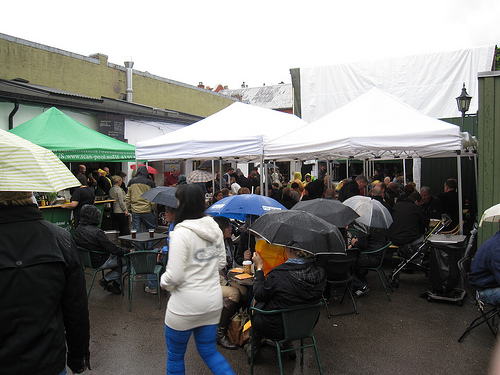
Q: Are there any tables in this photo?
A: Yes, there is a table.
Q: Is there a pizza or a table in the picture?
A: Yes, there is a table.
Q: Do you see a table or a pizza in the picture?
A: Yes, there is a table.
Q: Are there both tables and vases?
A: No, there is a table but no vases.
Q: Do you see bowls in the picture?
A: No, there are no bowls.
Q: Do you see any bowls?
A: No, there are no bowls.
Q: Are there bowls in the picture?
A: No, there are no bowls.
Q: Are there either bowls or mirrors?
A: No, there are no bowls or mirrors.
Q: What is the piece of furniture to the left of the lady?
A: The piece of furniture is a table.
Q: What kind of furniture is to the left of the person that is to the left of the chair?
A: The piece of furniture is a table.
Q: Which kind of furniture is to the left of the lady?
A: The piece of furniture is a table.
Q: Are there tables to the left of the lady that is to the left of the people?
A: Yes, there is a table to the left of the lady.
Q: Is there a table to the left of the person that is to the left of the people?
A: Yes, there is a table to the left of the lady.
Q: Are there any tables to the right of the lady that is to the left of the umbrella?
A: No, the table is to the left of the lady.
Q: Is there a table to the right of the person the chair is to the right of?
A: No, the table is to the left of the lady.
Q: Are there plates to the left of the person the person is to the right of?
A: No, there is a table to the left of the lady.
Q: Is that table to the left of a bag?
A: No, the table is to the left of a lady.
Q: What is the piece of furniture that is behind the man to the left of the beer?
A: The piece of furniture is a table.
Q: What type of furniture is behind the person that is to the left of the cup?
A: The piece of furniture is a table.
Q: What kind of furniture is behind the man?
A: The piece of furniture is a table.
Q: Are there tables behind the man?
A: Yes, there is a table behind the man.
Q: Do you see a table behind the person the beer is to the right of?
A: Yes, there is a table behind the man.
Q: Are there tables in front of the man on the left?
A: No, the table is behind the man.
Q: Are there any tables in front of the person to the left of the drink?
A: No, the table is behind the man.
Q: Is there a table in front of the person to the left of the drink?
A: No, the table is behind the man.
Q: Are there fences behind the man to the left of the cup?
A: No, there is a table behind the man.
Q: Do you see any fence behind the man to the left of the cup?
A: No, there is a table behind the man.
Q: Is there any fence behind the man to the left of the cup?
A: No, there is a table behind the man.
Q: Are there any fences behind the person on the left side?
A: No, there is a table behind the man.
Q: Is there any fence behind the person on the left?
A: No, there is a table behind the man.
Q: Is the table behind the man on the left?
A: Yes, the table is behind the man.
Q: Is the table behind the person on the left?
A: Yes, the table is behind the man.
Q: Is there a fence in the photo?
A: No, there are no fences.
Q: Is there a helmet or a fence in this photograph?
A: No, there are no fences or helmets.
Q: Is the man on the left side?
A: Yes, the man is on the left of the image.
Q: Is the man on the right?
A: No, the man is on the left of the image.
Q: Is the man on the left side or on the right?
A: The man is on the left of the image.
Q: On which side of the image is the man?
A: The man is on the left of the image.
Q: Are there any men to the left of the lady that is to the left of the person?
A: Yes, there is a man to the left of the lady.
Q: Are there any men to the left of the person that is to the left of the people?
A: Yes, there is a man to the left of the lady.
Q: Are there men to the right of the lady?
A: No, the man is to the left of the lady.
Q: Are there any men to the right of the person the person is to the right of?
A: No, the man is to the left of the lady.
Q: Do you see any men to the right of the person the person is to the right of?
A: No, the man is to the left of the lady.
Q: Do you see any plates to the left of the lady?
A: No, there is a man to the left of the lady.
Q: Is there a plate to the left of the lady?
A: No, there is a man to the left of the lady.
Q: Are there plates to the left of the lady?
A: No, there is a man to the left of the lady.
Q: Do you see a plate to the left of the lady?
A: No, there is a man to the left of the lady.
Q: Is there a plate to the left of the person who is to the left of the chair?
A: No, there is a man to the left of the lady.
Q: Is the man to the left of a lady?
A: Yes, the man is to the left of a lady.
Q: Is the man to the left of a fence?
A: No, the man is to the left of a lady.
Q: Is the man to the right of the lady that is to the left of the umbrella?
A: No, the man is to the left of the lady.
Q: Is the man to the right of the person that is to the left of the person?
A: No, the man is to the left of the lady.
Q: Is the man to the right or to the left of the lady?
A: The man is to the left of the lady.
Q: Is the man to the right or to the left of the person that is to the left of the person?
A: The man is to the left of the lady.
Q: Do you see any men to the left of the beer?
A: Yes, there is a man to the left of the beer.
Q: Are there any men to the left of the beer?
A: Yes, there is a man to the left of the beer.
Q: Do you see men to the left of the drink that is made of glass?
A: Yes, there is a man to the left of the beer.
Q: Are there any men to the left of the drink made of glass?
A: Yes, there is a man to the left of the beer.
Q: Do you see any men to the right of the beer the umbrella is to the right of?
A: No, the man is to the left of the beer.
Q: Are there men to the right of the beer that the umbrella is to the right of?
A: No, the man is to the left of the beer.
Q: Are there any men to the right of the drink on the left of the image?
A: No, the man is to the left of the beer.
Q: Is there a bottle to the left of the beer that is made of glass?
A: No, there is a man to the left of the beer.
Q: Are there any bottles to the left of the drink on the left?
A: No, there is a man to the left of the beer.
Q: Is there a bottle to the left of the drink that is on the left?
A: No, there is a man to the left of the beer.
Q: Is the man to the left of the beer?
A: Yes, the man is to the left of the beer.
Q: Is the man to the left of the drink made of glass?
A: Yes, the man is to the left of the beer.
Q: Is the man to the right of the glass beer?
A: No, the man is to the left of the beer.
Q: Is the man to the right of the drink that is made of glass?
A: No, the man is to the left of the beer.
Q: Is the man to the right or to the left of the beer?
A: The man is to the left of the beer.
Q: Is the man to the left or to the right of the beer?
A: The man is to the left of the beer.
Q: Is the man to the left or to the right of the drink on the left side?
A: The man is to the left of the beer.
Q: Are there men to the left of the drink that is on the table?
A: Yes, there is a man to the left of the drink.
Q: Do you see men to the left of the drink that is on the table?
A: Yes, there is a man to the left of the drink.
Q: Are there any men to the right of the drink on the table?
A: No, the man is to the left of the drink.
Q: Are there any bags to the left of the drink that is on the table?
A: No, there is a man to the left of the drink.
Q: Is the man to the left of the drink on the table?
A: Yes, the man is to the left of the drink.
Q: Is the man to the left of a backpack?
A: No, the man is to the left of the drink.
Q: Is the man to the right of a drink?
A: No, the man is to the left of a drink.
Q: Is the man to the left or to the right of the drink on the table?
A: The man is to the left of the drink.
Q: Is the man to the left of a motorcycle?
A: No, the man is to the left of the umbrella.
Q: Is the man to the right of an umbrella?
A: No, the man is to the left of an umbrella.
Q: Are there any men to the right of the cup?
A: No, the man is to the left of the cup.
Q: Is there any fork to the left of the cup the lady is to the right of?
A: No, there is a man to the left of the cup.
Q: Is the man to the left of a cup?
A: Yes, the man is to the left of a cup.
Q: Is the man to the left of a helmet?
A: No, the man is to the left of a cup.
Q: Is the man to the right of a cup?
A: No, the man is to the left of a cup.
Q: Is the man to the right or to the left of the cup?
A: The man is to the left of the cup.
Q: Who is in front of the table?
A: The man is in front of the table.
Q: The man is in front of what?
A: The man is in front of the table.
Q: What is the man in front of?
A: The man is in front of the table.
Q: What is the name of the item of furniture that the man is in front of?
A: The piece of furniture is a table.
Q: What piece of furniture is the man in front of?
A: The man is in front of the table.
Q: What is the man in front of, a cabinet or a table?
A: The man is in front of a table.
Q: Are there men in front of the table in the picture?
A: Yes, there is a man in front of the table.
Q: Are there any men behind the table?
A: No, the man is in front of the table.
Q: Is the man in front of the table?
A: Yes, the man is in front of the table.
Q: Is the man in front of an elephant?
A: No, the man is in front of the table.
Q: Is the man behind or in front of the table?
A: The man is in front of the table.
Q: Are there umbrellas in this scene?
A: Yes, there is an umbrella.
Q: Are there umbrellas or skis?
A: Yes, there is an umbrella.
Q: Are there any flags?
A: No, there are no flags.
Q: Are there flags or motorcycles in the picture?
A: No, there are no flags or motorcycles.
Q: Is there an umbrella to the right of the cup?
A: Yes, there is an umbrella to the right of the cup.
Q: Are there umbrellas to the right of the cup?
A: Yes, there is an umbrella to the right of the cup.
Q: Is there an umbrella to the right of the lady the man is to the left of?
A: Yes, there is an umbrella to the right of the lady.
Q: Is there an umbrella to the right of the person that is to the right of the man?
A: Yes, there is an umbrella to the right of the lady.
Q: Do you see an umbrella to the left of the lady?
A: No, the umbrella is to the right of the lady.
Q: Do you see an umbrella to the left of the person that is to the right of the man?
A: No, the umbrella is to the right of the lady.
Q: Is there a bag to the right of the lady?
A: No, there is an umbrella to the right of the lady.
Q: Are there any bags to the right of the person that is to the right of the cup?
A: No, there is an umbrella to the right of the lady.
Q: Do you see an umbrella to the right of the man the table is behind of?
A: Yes, there is an umbrella to the right of the man.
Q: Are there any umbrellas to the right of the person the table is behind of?
A: Yes, there is an umbrella to the right of the man.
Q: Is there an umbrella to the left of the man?
A: No, the umbrella is to the right of the man.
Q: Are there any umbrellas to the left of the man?
A: No, the umbrella is to the right of the man.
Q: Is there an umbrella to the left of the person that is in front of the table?
A: No, the umbrella is to the right of the man.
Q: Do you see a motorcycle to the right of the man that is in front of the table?
A: No, there is an umbrella to the right of the man.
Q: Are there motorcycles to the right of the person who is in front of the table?
A: No, there is an umbrella to the right of the man.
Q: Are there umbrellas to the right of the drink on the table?
A: Yes, there is an umbrella to the right of the drink.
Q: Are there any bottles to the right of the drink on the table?
A: No, there is an umbrella to the right of the drink.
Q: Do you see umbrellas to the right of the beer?
A: Yes, there is an umbrella to the right of the beer.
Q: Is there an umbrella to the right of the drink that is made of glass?
A: Yes, there is an umbrella to the right of the beer.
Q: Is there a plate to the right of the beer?
A: No, there is an umbrella to the right of the beer.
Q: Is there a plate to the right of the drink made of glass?
A: No, there is an umbrella to the right of the beer.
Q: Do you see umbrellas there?
A: Yes, there is an umbrella.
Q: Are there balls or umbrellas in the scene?
A: Yes, there is an umbrella.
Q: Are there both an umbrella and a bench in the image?
A: No, there is an umbrella but no benches.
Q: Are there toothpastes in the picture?
A: No, there are no toothpastes.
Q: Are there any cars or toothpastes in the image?
A: No, there are no toothpastes or cars.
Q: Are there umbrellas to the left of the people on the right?
A: Yes, there is an umbrella to the left of the people.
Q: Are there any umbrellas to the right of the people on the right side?
A: No, the umbrella is to the left of the people.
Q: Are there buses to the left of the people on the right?
A: No, there is an umbrella to the left of the people.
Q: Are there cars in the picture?
A: No, there are no cars.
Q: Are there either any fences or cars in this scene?
A: No, there are no cars or fences.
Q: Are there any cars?
A: No, there are no cars.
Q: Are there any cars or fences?
A: No, there are no cars or fences.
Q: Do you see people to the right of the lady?
A: Yes, there are people to the right of the lady.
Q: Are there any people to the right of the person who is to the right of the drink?
A: Yes, there are people to the right of the lady.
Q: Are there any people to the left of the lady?
A: No, the people are to the right of the lady.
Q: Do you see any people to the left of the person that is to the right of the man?
A: No, the people are to the right of the lady.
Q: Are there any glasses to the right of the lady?
A: No, there are people to the right of the lady.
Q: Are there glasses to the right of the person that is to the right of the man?
A: No, there are people to the right of the lady.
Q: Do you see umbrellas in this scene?
A: Yes, there is an umbrella.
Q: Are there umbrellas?
A: Yes, there is an umbrella.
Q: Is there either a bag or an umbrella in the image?
A: Yes, there is an umbrella.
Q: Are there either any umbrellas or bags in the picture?
A: Yes, there is an umbrella.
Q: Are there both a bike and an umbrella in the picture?
A: No, there is an umbrella but no bikes.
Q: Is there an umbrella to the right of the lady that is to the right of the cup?
A: Yes, there is an umbrella to the right of the lady.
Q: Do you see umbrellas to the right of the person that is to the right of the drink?
A: Yes, there is an umbrella to the right of the lady.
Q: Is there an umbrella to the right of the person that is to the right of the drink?
A: Yes, there is an umbrella to the right of the lady.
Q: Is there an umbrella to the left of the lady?
A: No, the umbrella is to the right of the lady.